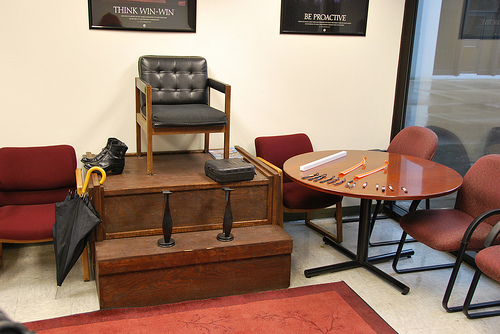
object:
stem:
[349, 195, 376, 267]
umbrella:
[52, 165, 105, 289]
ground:
[402, 294, 437, 327]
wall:
[230, 38, 412, 151]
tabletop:
[278, 145, 464, 198]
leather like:
[158, 66, 204, 97]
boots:
[80, 137, 128, 175]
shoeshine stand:
[77, 142, 293, 310]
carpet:
[18, 279, 397, 333]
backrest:
[136, 55, 210, 104]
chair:
[0, 142, 93, 280]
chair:
[132, 51, 234, 174]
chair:
[252, 128, 351, 244]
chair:
[399, 145, 497, 320]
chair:
[388, 122, 443, 160]